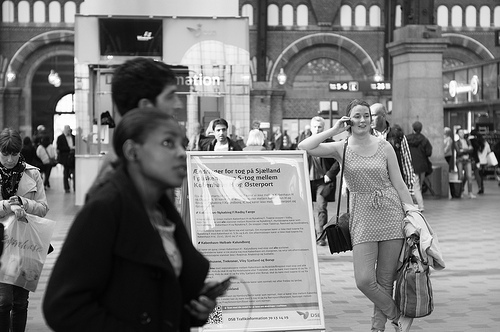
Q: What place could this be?
A: It is a train station.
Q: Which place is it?
A: It is a train station.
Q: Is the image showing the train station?
A: Yes, it is showing the train station.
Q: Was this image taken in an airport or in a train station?
A: It was taken at a train station.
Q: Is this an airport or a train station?
A: It is a train station.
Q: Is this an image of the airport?
A: No, the picture is showing the train station.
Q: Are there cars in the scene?
A: No, there are no cars.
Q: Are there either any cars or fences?
A: No, there are no cars or fences.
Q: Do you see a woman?
A: Yes, there is a woman.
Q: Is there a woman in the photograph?
A: Yes, there is a woman.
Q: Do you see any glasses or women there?
A: Yes, there is a woman.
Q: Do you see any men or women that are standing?
A: Yes, the woman is standing.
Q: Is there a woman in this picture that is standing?
A: Yes, there is a woman that is standing.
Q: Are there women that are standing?
A: Yes, there is a woman that is standing.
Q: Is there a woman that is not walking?
A: Yes, there is a woman that is standing.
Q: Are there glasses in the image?
A: No, there are no glasses.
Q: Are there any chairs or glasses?
A: No, there are no glasses or chairs.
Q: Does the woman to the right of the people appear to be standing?
A: Yes, the woman is standing.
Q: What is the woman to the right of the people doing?
A: The woman is standing.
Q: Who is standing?
A: The woman is standing.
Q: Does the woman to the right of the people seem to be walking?
A: No, the woman is standing.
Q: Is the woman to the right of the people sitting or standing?
A: The woman is standing.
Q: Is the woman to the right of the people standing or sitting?
A: The woman is standing.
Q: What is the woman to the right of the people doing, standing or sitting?
A: The woman is standing.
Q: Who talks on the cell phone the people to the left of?
A: The woman talks on the cell phone.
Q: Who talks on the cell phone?
A: The woman talks on the cell phone.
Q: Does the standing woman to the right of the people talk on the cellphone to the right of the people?
A: Yes, the woman talks on the cellphone.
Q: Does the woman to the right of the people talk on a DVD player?
A: No, the woman talks on the cellphone.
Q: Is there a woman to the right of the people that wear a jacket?
A: Yes, there is a woman to the right of the people.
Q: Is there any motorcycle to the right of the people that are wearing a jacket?
A: No, there is a woman to the right of the people.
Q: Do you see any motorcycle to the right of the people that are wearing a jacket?
A: No, there is a woman to the right of the people.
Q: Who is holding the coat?
A: The woman is holding the coat.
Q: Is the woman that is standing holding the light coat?
A: Yes, the woman is holding the coat.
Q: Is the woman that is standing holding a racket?
A: No, the woman is holding the coat.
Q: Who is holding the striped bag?
A: The woman is holding the purse.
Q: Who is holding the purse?
A: The woman is holding the purse.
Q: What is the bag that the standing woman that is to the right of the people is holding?
A: The bag is a purse.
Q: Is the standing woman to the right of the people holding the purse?
A: Yes, the woman is holding the purse.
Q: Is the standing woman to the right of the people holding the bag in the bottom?
A: Yes, the woman is holding the purse.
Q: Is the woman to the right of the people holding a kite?
A: No, the woman is holding the purse.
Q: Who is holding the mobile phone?
A: The woman is holding the mobile phone.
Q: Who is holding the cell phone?
A: The woman is holding the mobile phone.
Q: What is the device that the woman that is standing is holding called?
A: The device is a cell phone.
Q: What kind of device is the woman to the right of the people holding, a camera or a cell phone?
A: The woman is holding a cell phone.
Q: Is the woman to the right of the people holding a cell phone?
A: Yes, the woman is holding a cell phone.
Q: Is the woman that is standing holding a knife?
A: No, the woman is holding a cell phone.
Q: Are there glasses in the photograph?
A: No, there are no glasses.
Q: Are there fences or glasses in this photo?
A: No, there are no glasses or fences.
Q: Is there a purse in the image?
A: Yes, there is a purse.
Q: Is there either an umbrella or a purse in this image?
A: Yes, there is a purse.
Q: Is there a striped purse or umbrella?
A: Yes, there is a striped purse.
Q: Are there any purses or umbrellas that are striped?
A: Yes, the purse is striped.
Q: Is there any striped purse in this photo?
A: Yes, there is a striped purse.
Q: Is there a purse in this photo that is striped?
A: Yes, there is a purse that is striped.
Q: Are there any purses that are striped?
A: Yes, there is a purse that is striped.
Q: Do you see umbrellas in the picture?
A: No, there are no umbrellas.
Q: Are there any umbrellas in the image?
A: No, there are no umbrellas.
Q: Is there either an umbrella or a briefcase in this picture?
A: No, there are no umbrellas or briefcases.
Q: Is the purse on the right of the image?
A: Yes, the purse is on the right of the image.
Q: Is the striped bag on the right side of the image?
A: Yes, the purse is on the right of the image.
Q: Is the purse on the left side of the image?
A: No, the purse is on the right of the image.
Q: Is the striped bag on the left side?
A: No, the purse is on the right of the image.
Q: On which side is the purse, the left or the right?
A: The purse is on the right of the image.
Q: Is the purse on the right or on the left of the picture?
A: The purse is on the right of the image.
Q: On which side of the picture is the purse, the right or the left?
A: The purse is on the right of the image.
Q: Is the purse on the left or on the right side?
A: The purse is on the right of the image.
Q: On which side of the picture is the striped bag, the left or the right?
A: The purse is on the right of the image.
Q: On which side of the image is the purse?
A: The purse is on the right of the image.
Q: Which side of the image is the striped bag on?
A: The purse is on the right of the image.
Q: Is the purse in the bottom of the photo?
A: Yes, the purse is in the bottom of the image.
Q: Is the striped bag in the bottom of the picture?
A: Yes, the purse is in the bottom of the image.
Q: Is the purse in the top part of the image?
A: No, the purse is in the bottom of the image.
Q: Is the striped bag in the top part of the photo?
A: No, the purse is in the bottom of the image.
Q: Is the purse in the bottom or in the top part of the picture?
A: The purse is in the bottom of the image.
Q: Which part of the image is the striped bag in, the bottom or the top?
A: The purse is in the bottom of the image.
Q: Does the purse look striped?
A: Yes, the purse is striped.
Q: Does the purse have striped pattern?
A: Yes, the purse is striped.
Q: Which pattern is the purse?
A: The purse is striped.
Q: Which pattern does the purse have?
A: The purse has striped pattern.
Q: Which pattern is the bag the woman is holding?
A: The purse is striped.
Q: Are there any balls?
A: No, there are no balls.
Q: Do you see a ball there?
A: No, there are no balls.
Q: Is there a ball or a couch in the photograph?
A: No, there are no balls or couches.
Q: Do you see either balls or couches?
A: No, there are no balls or couches.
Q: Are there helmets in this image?
A: No, there are no helmets.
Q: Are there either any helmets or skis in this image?
A: No, there are no helmets or skis.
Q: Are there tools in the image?
A: No, there are no tools.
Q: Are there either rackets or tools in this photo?
A: No, there are no tools or rackets.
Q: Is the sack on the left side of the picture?
A: Yes, the sack is on the left of the image.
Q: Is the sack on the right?
A: No, the sack is on the left of the image.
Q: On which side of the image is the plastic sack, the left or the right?
A: The sack is on the left of the image.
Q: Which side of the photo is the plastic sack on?
A: The sack is on the left of the image.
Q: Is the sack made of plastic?
A: Yes, the sack is made of plastic.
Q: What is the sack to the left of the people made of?
A: The sack is made of plastic.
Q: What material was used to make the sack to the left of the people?
A: The sack is made of plastic.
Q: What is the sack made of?
A: The sack is made of plastic.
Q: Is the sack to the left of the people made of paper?
A: No, the sack is made of plastic.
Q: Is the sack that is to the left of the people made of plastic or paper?
A: The sack is made of plastic.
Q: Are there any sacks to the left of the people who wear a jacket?
A: Yes, there is a sack to the left of the people.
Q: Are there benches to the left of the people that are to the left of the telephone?
A: No, there is a sack to the left of the people.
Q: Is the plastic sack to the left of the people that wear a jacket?
A: Yes, the sack is to the left of the people.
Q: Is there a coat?
A: Yes, there is a coat.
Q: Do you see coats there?
A: Yes, there is a coat.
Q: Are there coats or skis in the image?
A: Yes, there is a coat.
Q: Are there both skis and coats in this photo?
A: No, there is a coat but no skis.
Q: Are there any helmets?
A: No, there are no helmets.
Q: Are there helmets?
A: No, there are no helmets.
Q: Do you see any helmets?
A: No, there are no helmets.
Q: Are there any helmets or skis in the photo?
A: No, there are no helmets or skis.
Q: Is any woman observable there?
A: Yes, there is a woman.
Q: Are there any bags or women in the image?
A: Yes, there is a woman.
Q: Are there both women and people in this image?
A: Yes, there are both a woman and people.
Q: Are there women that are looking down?
A: Yes, there is a woman that is looking down.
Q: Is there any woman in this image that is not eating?
A: Yes, there is a woman that is looking down.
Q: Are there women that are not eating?
A: Yes, there is a woman that is looking down.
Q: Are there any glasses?
A: No, there are no glasses.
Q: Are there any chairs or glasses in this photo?
A: No, there are no glasses or chairs.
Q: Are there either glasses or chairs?
A: No, there are no glasses or chairs.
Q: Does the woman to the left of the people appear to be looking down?
A: Yes, the woman is looking down.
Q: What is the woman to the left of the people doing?
A: The woman is looking down.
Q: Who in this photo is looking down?
A: The woman is looking down.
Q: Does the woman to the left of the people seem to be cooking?
A: No, the woman is looking down.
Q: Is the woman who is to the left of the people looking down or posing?
A: The woman is looking down.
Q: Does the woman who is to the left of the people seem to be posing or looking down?
A: The woman is looking down.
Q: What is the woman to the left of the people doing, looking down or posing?
A: The woman is looking down.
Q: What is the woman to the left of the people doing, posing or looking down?
A: The woman is looking down.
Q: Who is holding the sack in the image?
A: The woman is holding the sack.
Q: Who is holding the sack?
A: The woman is holding the sack.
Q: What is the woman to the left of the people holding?
A: The woman is holding the sack.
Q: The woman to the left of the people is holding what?
A: The woman is holding the sack.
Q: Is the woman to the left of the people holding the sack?
A: Yes, the woman is holding the sack.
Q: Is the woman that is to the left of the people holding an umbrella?
A: No, the woman is holding the sack.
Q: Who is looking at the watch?
A: The woman is looking at the watch.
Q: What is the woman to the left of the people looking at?
A: The woman is looking at the watch.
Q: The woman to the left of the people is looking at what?
A: The woman is looking at the watch.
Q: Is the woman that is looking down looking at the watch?
A: Yes, the woman is looking at the watch.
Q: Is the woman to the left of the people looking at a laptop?
A: No, the woman is looking at the watch.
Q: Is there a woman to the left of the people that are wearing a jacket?
A: Yes, there is a woman to the left of the people.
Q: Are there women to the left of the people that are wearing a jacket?
A: Yes, there is a woman to the left of the people.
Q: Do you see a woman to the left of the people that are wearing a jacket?
A: Yes, there is a woman to the left of the people.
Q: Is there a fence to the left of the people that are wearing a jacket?
A: No, there is a woman to the left of the people.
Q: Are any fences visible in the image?
A: No, there are no fences.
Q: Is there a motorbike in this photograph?
A: No, there are no motorcycles.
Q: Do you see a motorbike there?
A: No, there are no motorcycles.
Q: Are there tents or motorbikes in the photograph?
A: No, there are no motorbikes or tents.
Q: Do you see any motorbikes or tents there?
A: No, there are no motorbikes or tents.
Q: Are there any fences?
A: No, there are no fences.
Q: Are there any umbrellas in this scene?
A: No, there are no umbrellas.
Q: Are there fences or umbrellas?
A: No, there are no umbrellas or fences.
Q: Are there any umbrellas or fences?
A: No, there are no umbrellas or fences.